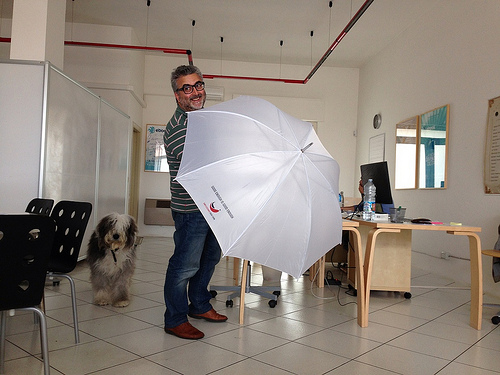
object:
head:
[103, 213, 141, 248]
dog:
[86, 210, 145, 308]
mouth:
[188, 94, 204, 102]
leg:
[362, 227, 401, 327]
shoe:
[165, 313, 204, 339]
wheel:
[401, 290, 412, 300]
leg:
[452, 230, 484, 329]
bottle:
[363, 178, 377, 220]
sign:
[394, 104, 450, 192]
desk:
[233, 208, 485, 328]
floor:
[0, 236, 499, 373]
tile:
[249, 340, 350, 374]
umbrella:
[173, 95, 345, 282]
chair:
[25, 196, 55, 218]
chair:
[47, 199, 93, 342]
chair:
[2, 216, 50, 359]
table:
[0, 206, 56, 240]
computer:
[359, 160, 396, 217]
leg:
[68, 274, 80, 345]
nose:
[191, 88, 201, 98]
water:
[362, 186, 374, 222]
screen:
[358, 162, 396, 206]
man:
[165, 68, 228, 340]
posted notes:
[431, 216, 464, 228]